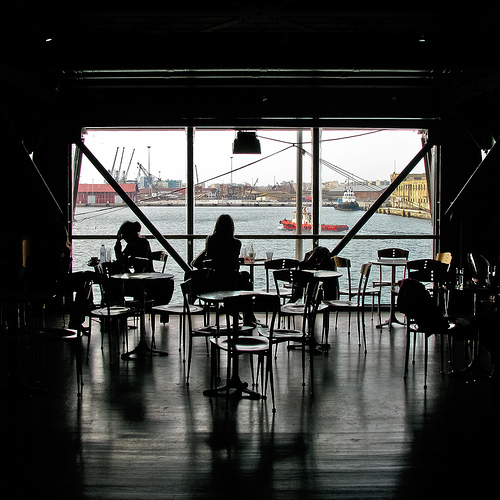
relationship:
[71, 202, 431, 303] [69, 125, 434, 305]
water seen out of window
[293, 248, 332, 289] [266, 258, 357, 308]
head on table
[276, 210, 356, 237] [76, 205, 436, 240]
boat in water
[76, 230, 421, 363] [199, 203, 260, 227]
seating area by water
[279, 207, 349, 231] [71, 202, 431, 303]
boat in water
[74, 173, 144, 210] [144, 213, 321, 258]
building near water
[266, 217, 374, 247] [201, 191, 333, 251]
tugboat on water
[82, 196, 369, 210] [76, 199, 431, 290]
partition on water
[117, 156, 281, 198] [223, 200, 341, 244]
structures on water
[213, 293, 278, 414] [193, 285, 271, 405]
chair on table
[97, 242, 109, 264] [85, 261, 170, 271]
plastic bottle on table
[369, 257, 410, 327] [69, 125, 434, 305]
table on window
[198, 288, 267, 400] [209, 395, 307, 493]
table throwing off shadows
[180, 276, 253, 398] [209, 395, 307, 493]
chair throwing off shadows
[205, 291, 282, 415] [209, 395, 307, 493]
chair throwing off shadows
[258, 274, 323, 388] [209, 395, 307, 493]
chair throwing off shadows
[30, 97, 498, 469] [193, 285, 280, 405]
room with table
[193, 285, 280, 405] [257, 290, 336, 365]
table and chair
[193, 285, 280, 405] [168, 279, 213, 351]
table and chair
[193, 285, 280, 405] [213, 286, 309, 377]
table and chair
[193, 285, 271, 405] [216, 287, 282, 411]
table and chair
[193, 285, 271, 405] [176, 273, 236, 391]
table and chair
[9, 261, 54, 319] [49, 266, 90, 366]
table and chair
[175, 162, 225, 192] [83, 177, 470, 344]
sky over seaport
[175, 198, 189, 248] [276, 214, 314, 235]
water beneath boats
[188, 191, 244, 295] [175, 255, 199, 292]
woman sitting in chair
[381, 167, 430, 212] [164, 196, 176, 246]
building by water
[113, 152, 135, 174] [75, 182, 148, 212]
cranes sre behind building